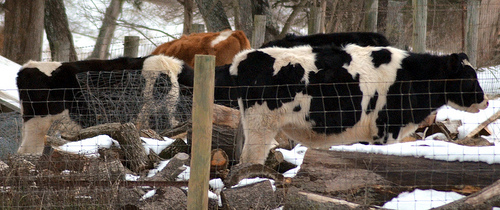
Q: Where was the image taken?
A: It was taken at the field.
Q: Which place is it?
A: It is a field.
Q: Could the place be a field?
A: Yes, it is a field.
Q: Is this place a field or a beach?
A: It is a field.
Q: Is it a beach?
A: No, it is a field.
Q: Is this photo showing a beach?
A: No, the picture is showing a field.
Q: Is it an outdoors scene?
A: Yes, it is outdoors.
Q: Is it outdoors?
A: Yes, it is outdoors.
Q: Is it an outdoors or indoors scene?
A: It is outdoors.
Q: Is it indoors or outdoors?
A: It is outdoors.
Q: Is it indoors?
A: No, it is outdoors.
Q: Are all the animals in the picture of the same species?
A: Yes, all the animals are cows.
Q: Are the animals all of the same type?
A: Yes, all the animals are cows.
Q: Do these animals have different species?
A: No, all the animals are cows.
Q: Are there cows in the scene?
A: Yes, there is a cow.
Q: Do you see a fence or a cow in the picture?
A: Yes, there is a cow.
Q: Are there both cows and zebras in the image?
A: No, there is a cow but no zebras.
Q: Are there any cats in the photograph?
A: No, there are no cats.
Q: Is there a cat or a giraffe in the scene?
A: No, there are no cats or giraffes.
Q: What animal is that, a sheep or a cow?
A: That is a cow.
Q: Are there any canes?
A: No, there are no canes.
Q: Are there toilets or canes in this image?
A: No, there are no canes or toilets.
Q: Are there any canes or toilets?
A: No, there are no canes or toilets.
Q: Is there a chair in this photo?
A: No, there are no chairs.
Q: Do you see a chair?
A: No, there are no chairs.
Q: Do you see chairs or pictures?
A: No, there are no chairs or pictures.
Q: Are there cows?
A: Yes, there is a cow.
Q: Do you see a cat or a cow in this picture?
A: Yes, there is a cow.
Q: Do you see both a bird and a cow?
A: No, there is a cow but no birds.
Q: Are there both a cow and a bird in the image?
A: No, there is a cow but no birds.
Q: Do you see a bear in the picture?
A: No, there are no bears.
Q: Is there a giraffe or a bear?
A: No, there are no bears or giraffes.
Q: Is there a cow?
A: Yes, there is a cow.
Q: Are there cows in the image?
A: Yes, there is a cow.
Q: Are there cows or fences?
A: Yes, there is a cow.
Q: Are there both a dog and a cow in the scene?
A: No, there is a cow but no dogs.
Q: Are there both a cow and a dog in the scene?
A: No, there is a cow but no dogs.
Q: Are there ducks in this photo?
A: No, there are no ducks.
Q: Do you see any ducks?
A: No, there are no ducks.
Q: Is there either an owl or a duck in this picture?
A: No, there are no ducks or owls.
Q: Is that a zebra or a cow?
A: That is a cow.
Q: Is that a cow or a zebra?
A: That is a cow.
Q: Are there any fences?
A: Yes, there is a fence.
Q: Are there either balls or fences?
A: Yes, there is a fence.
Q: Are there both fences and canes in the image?
A: No, there is a fence but no canes.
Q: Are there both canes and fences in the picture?
A: No, there is a fence but no canes.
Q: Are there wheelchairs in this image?
A: No, there are no wheelchairs.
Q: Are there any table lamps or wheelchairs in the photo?
A: No, there are no wheelchairs or table lamps.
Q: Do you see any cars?
A: No, there are no cars.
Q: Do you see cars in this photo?
A: No, there are no cars.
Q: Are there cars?
A: No, there are no cars.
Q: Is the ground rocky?
A: Yes, the ground is rocky.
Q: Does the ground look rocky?
A: Yes, the ground is rocky.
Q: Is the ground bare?
A: No, the ground is rocky.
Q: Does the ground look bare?
A: No, the ground is rocky.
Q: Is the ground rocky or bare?
A: The ground is rocky.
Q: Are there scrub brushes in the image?
A: No, there are no scrub brushes.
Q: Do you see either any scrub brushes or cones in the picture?
A: No, there are no scrub brushes or cones.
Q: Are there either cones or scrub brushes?
A: No, there are no scrub brushes or cones.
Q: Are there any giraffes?
A: No, there are no giraffes.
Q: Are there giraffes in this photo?
A: No, there are no giraffes.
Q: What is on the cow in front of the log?
A: The spots are on the cow.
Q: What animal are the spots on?
A: The spots are on the cow.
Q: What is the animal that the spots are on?
A: The animal is a cow.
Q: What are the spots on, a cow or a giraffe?
A: The spots are on a cow.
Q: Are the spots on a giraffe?
A: No, the spots are on the cow.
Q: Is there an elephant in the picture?
A: No, there are no elephants.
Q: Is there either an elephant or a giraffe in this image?
A: No, there are no elephants or giraffes.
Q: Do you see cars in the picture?
A: No, there are no cars.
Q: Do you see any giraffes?
A: No, there are no giraffes.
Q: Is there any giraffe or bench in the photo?
A: No, there are no giraffes or benches.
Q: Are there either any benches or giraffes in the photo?
A: No, there are no giraffes or benches.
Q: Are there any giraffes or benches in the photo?
A: No, there are no giraffes or benches.